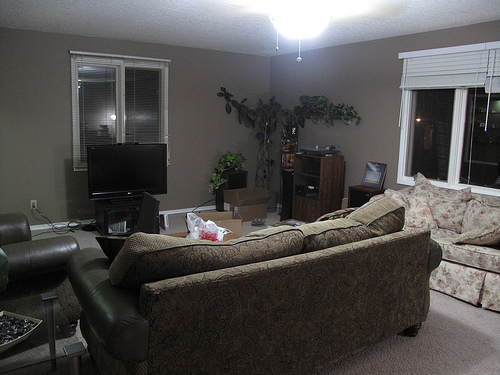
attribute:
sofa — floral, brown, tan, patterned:
[67, 194, 443, 374]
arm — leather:
[69, 247, 150, 363]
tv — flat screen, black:
[86, 143, 168, 198]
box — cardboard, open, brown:
[223, 184, 271, 222]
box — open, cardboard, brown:
[191, 210, 244, 239]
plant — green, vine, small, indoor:
[207, 150, 246, 192]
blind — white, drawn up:
[397, 43, 489, 129]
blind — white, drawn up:
[484, 41, 498, 131]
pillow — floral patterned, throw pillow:
[384, 187, 438, 231]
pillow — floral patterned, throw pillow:
[453, 222, 499, 245]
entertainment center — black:
[97, 197, 160, 232]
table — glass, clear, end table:
[0, 289, 87, 374]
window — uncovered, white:
[398, 88, 500, 197]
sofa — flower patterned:
[371, 171, 499, 314]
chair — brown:
[0, 212, 81, 336]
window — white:
[71, 53, 170, 170]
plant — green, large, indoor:
[217, 85, 290, 211]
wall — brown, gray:
[0, 29, 272, 225]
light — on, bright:
[271, 11, 331, 42]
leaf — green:
[226, 102, 233, 114]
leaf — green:
[241, 95, 248, 105]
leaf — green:
[216, 91, 224, 97]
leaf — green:
[224, 91, 233, 98]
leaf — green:
[236, 111, 243, 124]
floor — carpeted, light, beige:
[317, 286, 499, 374]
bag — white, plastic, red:
[186, 210, 231, 242]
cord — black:
[33, 207, 102, 233]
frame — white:
[70, 53, 175, 172]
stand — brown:
[289, 152, 346, 222]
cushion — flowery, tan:
[410, 172, 471, 231]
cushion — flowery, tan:
[462, 195, 499, 228]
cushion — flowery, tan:
[429, 233, 499, 273]